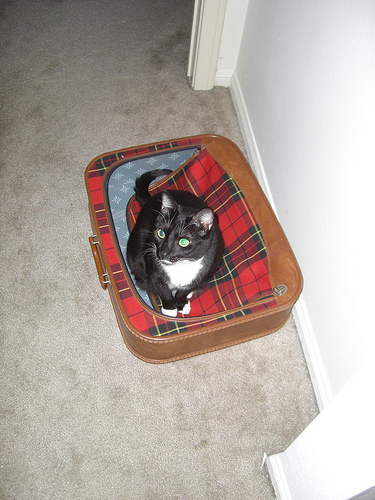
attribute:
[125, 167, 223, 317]
cat — white, black, black and white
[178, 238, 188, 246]
eye — left eye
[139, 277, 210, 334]
paw — black , white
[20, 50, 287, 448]
carpeting — Brown 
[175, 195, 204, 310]
hair — black , white 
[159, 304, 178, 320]
paw — white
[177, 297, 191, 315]
paw — white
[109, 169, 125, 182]
design — white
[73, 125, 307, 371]
suitcase — plaid , leather 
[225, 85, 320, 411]
baseboard — white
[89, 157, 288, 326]
plaid suitcase — unzipped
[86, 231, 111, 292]
handle — brown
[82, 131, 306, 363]
luggage — plaid, blue , inside ,  piece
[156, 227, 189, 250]
eyes — Green 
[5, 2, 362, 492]
room — corner 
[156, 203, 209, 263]
face — black cat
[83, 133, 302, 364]
suitcase — plaid